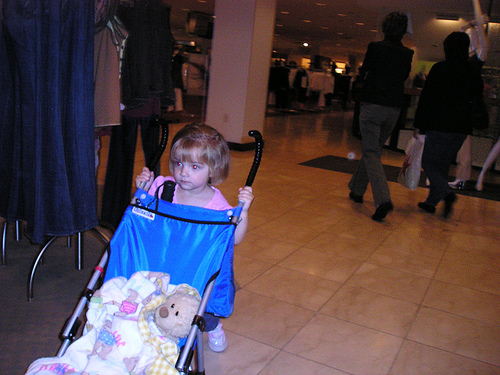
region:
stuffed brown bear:
[141, 289, 214, 356]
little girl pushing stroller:
[159, 113, 276, 254]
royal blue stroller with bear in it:
[30, 115, 307, 373]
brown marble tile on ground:
[321, 212, 396, 337]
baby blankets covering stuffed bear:
[58, 285, 173, 373]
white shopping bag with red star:
[390, 121, 432, 198]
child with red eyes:
[174, 148, 209, 180]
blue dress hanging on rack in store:
[16, 23, 123, 267]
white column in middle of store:
[216, 68, 271, 105]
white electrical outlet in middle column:
[209, 93, 263, 134]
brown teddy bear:
[142, 288, 207, 335]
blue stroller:
[29, 119, 272, 370]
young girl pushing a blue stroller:
[113, 115, 283, 350]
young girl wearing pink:
[162, 120, 234, 219]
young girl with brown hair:
[164, 115, 231, 192]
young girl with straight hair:
[162, 114, 232, 195]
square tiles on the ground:
[253, 211, 447, 370]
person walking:
[342, 6, 417, 227]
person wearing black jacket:
[347, 9, 422, 120]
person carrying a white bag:
[395, 17, 479, 238]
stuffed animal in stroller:
[149, 289, 202, 341]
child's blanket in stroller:
[25, 265, 178, 372]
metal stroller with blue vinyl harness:
[12, 108, 264, 374]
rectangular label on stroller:
[129, 204, 156, 220]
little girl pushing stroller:
[135, 118, 255, 360]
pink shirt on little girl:
[147, 170, 233, 209]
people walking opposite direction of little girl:
[337, 4, 485, 239]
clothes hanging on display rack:
[2, 0, 173, 253]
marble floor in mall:
[116, 112, 498, 374]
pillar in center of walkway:
[205, 3, 276, 152]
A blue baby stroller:
[52, 116, 264, 373]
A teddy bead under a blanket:
[31, 273, 201, 371]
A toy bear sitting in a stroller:
[24, 272, 202, 374]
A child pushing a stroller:
[6, 123, 261, 373]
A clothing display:
[0, 5, 180, 297]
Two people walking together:
[348, 12, 484, 221]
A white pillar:
[204, 0, 274, 152]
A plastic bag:
[398, 131, 423, 191]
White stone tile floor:
[94, 108, 499, 372]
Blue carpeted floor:
[2, 184, 113, 373]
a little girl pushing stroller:
[26, 114, 265, 374]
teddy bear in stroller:
[87, 284, 204, 373]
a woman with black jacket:
[347, 9, 416, 222]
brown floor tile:
[0, 107, 499, 373]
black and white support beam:
[203, 0, 280, 155]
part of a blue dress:
[0, 0, 98, 245]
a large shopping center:
[0, 0, 497, 373]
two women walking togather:
[348, 8, 489, 219]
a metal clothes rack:
[0, 122, 116, 304]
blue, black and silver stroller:
[27, 114, 266, 372]